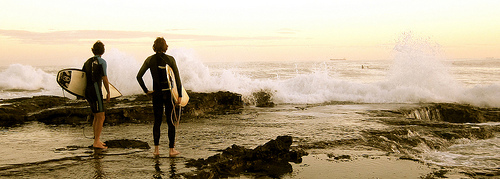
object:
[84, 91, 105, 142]
leg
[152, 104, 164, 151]
leg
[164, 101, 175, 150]
leg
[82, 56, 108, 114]
gear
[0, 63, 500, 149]
water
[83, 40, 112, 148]
man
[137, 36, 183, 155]
man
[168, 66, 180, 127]
cable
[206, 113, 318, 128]
ripple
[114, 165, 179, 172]
ripple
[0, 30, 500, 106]
wave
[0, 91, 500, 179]
shore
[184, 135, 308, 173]
rock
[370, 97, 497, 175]
ground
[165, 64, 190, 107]
board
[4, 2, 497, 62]
sky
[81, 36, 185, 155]
men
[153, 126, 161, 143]
calf muscles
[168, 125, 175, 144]
calf muscles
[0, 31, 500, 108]
object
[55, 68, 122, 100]
board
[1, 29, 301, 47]
clouds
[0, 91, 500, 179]
beach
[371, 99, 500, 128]
depresion